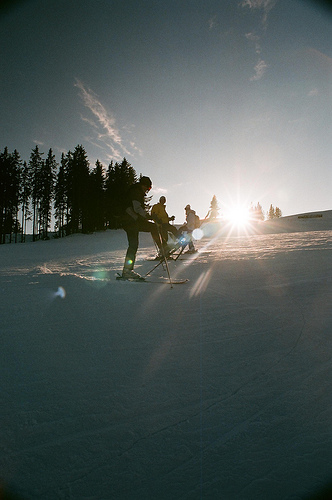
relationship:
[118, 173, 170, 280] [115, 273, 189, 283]
people wearing skis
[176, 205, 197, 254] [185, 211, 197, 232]
person wearing jacket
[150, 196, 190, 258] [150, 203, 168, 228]
person wearing jacket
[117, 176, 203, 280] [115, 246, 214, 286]
people wearing skis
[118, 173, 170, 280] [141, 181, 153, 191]
people wearing goggles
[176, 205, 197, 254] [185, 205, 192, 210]
person wearing hat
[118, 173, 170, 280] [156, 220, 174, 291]
people holding ski pole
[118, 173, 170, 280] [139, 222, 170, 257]
people has leg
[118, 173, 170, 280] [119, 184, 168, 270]
people wearing outfit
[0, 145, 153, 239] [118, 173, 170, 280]
pine trees behind people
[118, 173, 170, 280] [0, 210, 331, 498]
people on top of hill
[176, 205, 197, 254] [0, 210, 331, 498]
person on top of hill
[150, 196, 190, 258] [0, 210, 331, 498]
person on top of hill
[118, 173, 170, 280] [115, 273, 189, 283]
people on top of skis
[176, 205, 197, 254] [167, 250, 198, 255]
person on top of skis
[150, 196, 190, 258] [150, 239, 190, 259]
person on top of skis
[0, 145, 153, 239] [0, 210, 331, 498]
pine trees beside hill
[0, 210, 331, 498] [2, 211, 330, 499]
hill covered in snow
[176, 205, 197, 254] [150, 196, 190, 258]
person talking to person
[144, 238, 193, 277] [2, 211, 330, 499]
ski above snow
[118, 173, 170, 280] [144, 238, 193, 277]
people has ski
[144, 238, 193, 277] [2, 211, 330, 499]
ski lifted above snow